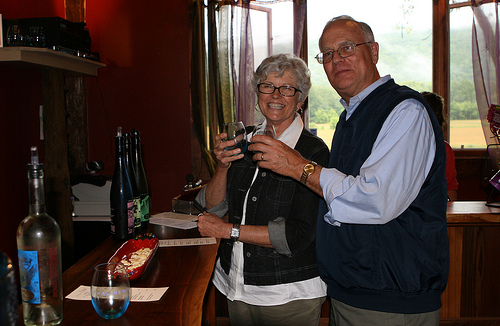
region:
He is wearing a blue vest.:
[307, 86, 449, 278]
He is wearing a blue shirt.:
[325, 71, 449, 248]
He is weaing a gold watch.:
[287, 152, 327, 214]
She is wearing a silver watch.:
[203, 211, 258, 282]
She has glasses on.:
[245, 76, 295, 104]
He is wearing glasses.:
[297, 25, 405, 79]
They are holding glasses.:
[207, 111, 311, 202]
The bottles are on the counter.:
[95, 116, 167, 226]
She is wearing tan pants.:
[227, 278, 287, 323]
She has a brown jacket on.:
[243, 151, 345, 293]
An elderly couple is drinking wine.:
[221, 41, 408, 205]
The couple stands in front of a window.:
[202, 8, 484, 138]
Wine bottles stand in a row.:
[77, 124, 192, 319]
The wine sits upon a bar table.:
[20, 175, 202, 315]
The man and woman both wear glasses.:
[252, 42, 387, 127]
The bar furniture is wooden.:
[162, 255, 210, 325]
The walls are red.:
[115, 30, 171, 121]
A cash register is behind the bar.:
[82, 170, 111, 230]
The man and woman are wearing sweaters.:
[275, 132, 412, 262]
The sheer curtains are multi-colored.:
[217, 8, 257, 124]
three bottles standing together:
[97, 128, 175, 235]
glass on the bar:
[56, 246, 169, 320]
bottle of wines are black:
[114, 123, 159, 236]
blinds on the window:
[217, 1, 267, 142]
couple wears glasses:
[255, 44, 395, 152]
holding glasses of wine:
[214, 114, 324, 165]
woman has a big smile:
[237, 93, 311, 119]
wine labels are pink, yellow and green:
[113, 189, 157, 233]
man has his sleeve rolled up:
[315, 166, 378, 269]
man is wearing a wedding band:
[249, 146, 282, 173]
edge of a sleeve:
[258, 212, 290, 256]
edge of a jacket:
[315, 267, 370, 322]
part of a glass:
[81, 250, 129, 307]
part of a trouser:
[264, 294, 289, 319]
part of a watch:
[297, 150, 317, 190]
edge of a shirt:
[232, 285, 262, 307]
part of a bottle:
[122, 204, 137, 226]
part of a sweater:
[341, 105, 369, 141]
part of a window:
[441, 45, 471, 111]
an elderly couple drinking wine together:
[190, 14, 465, 323]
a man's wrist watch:
[300, 158, 315, 186]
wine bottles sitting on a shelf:
[109, 131, 152, 236]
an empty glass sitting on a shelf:
[89, 260, 131, 319]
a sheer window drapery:
[470, 5, 498, 152]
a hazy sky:
[371, 8, 428, 33]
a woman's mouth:
[264, 102, 286, 111]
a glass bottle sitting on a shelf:
[19, 140, 70, 322]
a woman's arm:
[194, 210, 269, 247]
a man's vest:
[380, 232, 445, 293]